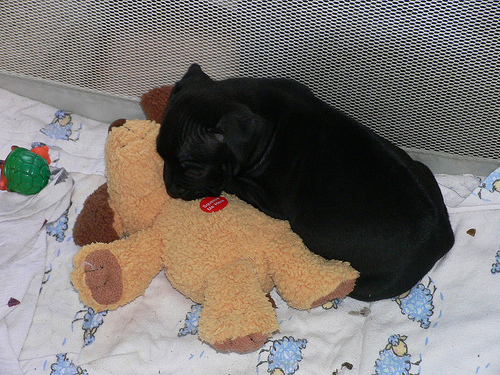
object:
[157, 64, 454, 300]
puppy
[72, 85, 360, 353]
puppy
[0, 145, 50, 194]
turtle ball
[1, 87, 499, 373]
blanket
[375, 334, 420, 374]
sheep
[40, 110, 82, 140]
sheep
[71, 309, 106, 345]
sheep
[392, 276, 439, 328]
sheep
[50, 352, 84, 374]
sheep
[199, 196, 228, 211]
tag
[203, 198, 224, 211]
squeeze me here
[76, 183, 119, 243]
ears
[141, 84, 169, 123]
ears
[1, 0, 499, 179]
cage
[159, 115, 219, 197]
wrinkly face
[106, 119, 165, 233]
head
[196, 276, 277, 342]
leg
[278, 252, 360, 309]
leg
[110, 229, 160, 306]
arm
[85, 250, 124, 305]
paw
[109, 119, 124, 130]
nose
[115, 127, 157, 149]
mouth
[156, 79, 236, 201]
head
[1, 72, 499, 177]
edge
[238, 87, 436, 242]
back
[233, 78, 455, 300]
body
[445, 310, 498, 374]
part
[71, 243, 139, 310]
hand